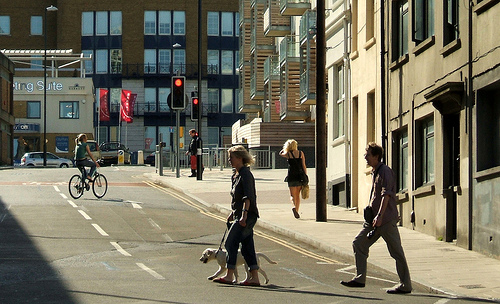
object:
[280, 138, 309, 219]
woman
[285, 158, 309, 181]
dress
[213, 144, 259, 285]
woman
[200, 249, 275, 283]
dog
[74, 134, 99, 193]
woman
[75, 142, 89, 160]
shirt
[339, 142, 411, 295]
man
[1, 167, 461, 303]
street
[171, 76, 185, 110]
light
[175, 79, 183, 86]
red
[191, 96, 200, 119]
light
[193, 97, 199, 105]
red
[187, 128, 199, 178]
man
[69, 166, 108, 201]
bike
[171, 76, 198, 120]
stoplights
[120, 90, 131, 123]
flag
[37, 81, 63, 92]
word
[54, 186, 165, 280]
line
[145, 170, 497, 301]
sidewalk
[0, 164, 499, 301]
hill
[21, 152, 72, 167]
car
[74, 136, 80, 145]
ponytail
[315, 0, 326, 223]
pole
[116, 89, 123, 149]
pole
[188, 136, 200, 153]
jacket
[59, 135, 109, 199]
traffic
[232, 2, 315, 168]
building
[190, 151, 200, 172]
pants